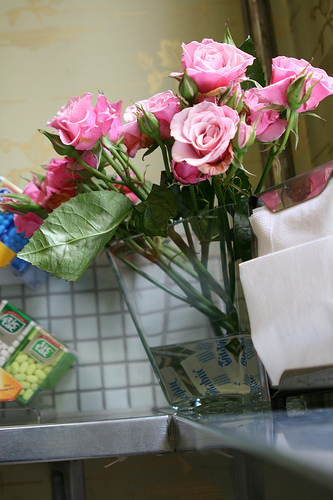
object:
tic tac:
[44, 365, 53, 374]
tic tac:
[33, 365, 46, 382]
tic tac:
[14, 353, 27, 364]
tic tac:
[21, 388, 32, 400]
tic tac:
[24, 361, 34, 375]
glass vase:
[107, 201, 268, 410]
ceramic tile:
[14, 281, 173, 414]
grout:
[93, 290, 109, 403]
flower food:
[161, 351, 252, 395]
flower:
[157, 99, 244, 178]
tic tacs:
[1, 324, 78, 408]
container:
[2, 324, 78, 412]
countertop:
[56, 252, 263, 406]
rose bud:
[130, 98, 159, 137]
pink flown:
[5, 93, 144, 239]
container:
[0, 175, 28, 276]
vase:
[97, 208, 289, 446]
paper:
[235, 254, 314, 291]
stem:
[92, 155, 175, 222]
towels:
[220, 195, 327, 374]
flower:
[176, 35, 248, 85]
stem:
[257, 151, 276, 183]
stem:
[180, 197, 268, 355]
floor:
[0, 202, 268, 423]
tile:
[48, 293, 73, 316]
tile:
[72, 291, 96, 315]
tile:
[94, 289, 122, 316]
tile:
[74, 316, 99, 339]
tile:
[98, 314, 123, 338]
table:
[7, 415, 199, 454]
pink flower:
[6, 184, 44, 228]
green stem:
[18, 191, 57, 226]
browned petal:
[196, 144, 235, 176]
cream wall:
[1, 1, 252, 190]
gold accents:
[135, 36, 183, 92]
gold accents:
[0, 2, 150, 49]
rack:
[265, 359, 321, 397]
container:
[0, 291, 38, 367]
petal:
[201, 146, 232, 175]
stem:
[207, 172, 236, 302]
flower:
[46, 89, 116, 151]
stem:
[84, 130, 242, 339]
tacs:
[2, 329, 63, 399]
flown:
[5, 10, 322, 291]